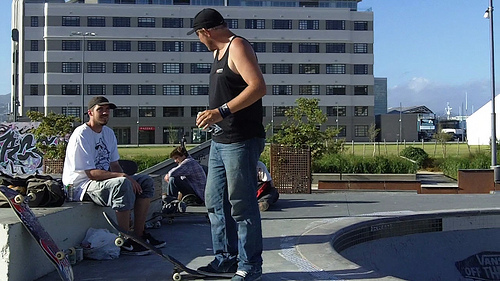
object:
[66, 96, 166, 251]
man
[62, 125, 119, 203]
shirt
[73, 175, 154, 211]
shorts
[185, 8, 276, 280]
man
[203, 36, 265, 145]
shirt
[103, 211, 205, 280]
skateboard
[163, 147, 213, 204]
man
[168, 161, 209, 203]
shirt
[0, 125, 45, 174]
graffiti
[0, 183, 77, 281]
skateboard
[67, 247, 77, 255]
wheels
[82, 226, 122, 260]
bag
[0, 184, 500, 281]
concrete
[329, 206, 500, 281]
park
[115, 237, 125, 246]
wheel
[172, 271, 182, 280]
wheel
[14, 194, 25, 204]
wheel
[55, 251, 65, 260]
wheel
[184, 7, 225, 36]
hat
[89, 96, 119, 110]
hat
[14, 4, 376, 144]
building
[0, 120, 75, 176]
wall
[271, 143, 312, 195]
cage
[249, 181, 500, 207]
sidewalk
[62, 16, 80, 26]
window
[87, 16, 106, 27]
window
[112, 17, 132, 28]
window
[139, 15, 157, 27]
window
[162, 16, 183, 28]
window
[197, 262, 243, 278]
foot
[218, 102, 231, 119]
band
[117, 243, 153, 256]
nike